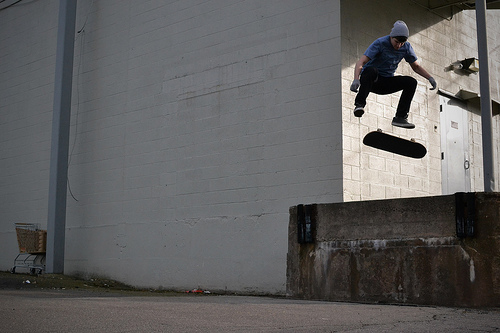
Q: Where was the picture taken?
A: A loading dock.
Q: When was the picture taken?
A: Daytime.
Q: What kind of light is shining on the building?
A: Sunlight.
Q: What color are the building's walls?
A: White.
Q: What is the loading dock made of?
A: Concrete.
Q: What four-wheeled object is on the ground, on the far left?
A: A shopping cart.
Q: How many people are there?
A: One.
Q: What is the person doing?
A: Skateboarding.